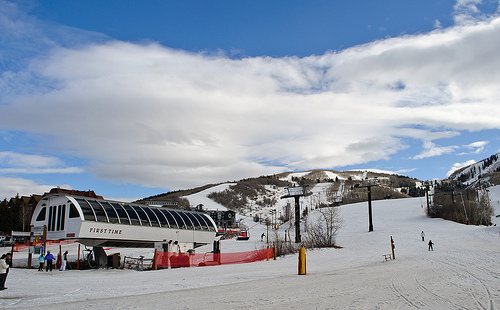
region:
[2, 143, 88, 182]
long white clouds in blue sky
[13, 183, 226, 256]
white building in snow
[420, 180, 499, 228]
fence upright in snow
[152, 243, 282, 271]
red netting running across snow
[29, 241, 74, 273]
people standing in snow in front of building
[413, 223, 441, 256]
two people skiing down snow slope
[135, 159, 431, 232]
snow covered mountain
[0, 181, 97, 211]
roofs of buildings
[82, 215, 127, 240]
words on side of white building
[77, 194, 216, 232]
row of windows on top of white building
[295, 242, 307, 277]
a yellow pole in the snow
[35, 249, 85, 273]
a group of people in line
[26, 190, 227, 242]
the entrance to a ski lift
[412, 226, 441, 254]
two people riding down a mountain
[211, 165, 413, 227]
a tall snowy mountain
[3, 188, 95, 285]
a line of people at the ski lift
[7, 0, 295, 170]
a cloudy blue day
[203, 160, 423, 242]
a snowy ski mountain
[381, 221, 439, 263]
a group of people riding the slopes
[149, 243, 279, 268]
a red mesh fence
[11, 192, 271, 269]
white building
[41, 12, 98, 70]
white clouds in blue sky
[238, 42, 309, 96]
white clouds in blue sky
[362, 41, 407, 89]
white clouds in blue sky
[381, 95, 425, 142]
white clouds in blue sky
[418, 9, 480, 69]
white clouds in blue sky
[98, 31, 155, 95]
white clouds in blue sky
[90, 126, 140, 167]
white clouds in blue sky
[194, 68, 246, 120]
white clouds in blue sky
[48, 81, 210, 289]
this is a building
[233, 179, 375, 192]
this is a mountain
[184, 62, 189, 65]
this is a cloud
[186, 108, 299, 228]
the cloud is white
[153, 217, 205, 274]
this is a fence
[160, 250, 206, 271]
the fence is orange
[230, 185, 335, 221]
this is a black pole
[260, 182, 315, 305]
the pole is large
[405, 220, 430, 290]
these are two people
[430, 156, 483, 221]
this is a bush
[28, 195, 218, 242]
white and black building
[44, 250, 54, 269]
person wearing blue jacket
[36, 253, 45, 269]
person wearing aqua jacket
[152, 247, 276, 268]
red mesh fence on snow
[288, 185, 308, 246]
light on black pole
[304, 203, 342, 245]
tree with no leaves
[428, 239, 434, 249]
person skiing on hill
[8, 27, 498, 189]
white clouds in sky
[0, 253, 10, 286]
person wearing white jacket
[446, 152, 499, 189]
snow covered hill top